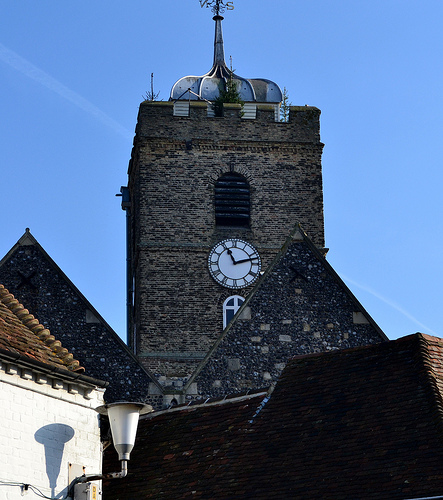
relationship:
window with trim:
[226, 300, 239, 331] [222, 293, 249, 332]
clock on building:
[179, 215, 336, 350] [113, 0, 331, 394]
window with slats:
[208, 167, 255, 237] [214, 178, 250, 216]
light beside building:
[98, 397, 151, 474] [0, 283, 112, 498]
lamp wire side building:
[7, 466, 49, 498] [12, 362, 104, 472]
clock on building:
[179, 215, 336, 350] [99, 8, 359, 407]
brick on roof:
[306, 393, 339, 418] [249, 334, 435, 491]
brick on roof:
[323, 393, 330, 409] [249, 334, 435, 491]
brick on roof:
[311, 405, 342, 414] [249, 334, 435, 491]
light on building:
[98, 397, 151, 474] [0, 283, 112, 498]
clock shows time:
[179, 215, 336, 350] [207, 240, 260, 281]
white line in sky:
[4, 46, 134, 145] [2, 2, 440, 343]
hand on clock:
[221, 243, 237, 265] [155, 205, 310, 329]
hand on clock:
[233, 254, 259, 264] [155, 205, 310, 329]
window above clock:
[208, 167, 255, 237] [179, 215, 336, 350]